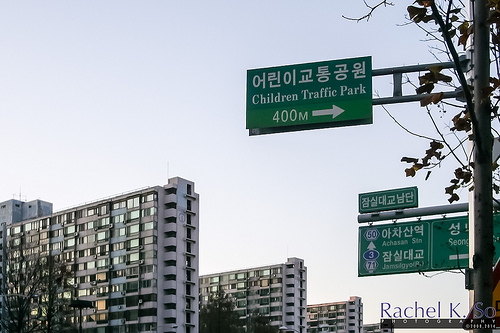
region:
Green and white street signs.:
[240, 51, 481, 286]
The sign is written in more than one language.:
[234, 45, 381, 135]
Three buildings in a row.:
[1, 171, 368, 330]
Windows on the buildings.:
[2, 192, 355, 331]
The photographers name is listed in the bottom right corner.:
[372, 297, 498, 332]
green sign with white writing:
[245, 54, 372, 134]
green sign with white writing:
[359, 185, 419, 211]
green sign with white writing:
[360, 223, 467, 280]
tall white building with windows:
[2, 178, 195, 330]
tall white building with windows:
[200, 256, 307, 331]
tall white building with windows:
[302, 295, 364, 331]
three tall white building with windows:
[0, 177, 365, 331]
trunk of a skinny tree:
[465, 0, 492, 332]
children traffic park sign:
[219, 47, 383, 142]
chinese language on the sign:
[240, 65, 370, 81]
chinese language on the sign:
[348, 185, 434, 206]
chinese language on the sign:
[378, 223, 434, 239]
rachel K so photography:
[380, 293, 497, 331]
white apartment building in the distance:
[196, 263, 321, 331]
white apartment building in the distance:
[297, 293, 375, 331]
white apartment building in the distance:
[367, 316, 398, 331]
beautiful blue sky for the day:
[50, 9, 219, 149]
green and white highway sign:
[241, 61, 383, 132]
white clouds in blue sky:
[51, 12, 83, 43]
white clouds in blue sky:
[144, 141, 175, 156]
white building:
[201, 262, 309, 319]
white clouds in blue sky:
[138, 22, 178, 73]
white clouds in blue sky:
[221, 159, 276, 190]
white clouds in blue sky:
[251, 153, 286, 201]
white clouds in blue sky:
[117, 52, 178, 107]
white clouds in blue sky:
[60, 53, 134, 108]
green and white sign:
[247, 54, 372, 134]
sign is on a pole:
[357, 186, 415, 210]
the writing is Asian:
[382, 225, 421, 237]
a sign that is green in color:
[227, 55, 392, 159]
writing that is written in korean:
[232, 55, 374, 90]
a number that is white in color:
[254, 93, 304, 137]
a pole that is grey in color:
[362, 55, 453, 117]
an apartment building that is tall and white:
[54, 159, 225, 331]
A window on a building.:
[124, 199, 139, 209]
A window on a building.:
[141, 205, 155, 213]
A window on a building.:
[141, 221, 154, 228]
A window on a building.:
[93, 258, 107, 263]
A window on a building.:
[128, 241, 138, 246]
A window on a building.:
[113, 285, 121, 291]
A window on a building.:
[262, 268, 272, 274]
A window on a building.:
[241, 273, 250, 276]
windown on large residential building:
[127, 196, 133, 208]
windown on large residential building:
[132, 197, 140, 207]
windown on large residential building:
[125, 209, 138, 219]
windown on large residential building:
[128, 223, 140, 233]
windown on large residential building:
[128, 238, 138, 248]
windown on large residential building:
[128, 251, 139, 261]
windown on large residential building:
[95, 230, 105, 239]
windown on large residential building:
[236, 272, 244, 279]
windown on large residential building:
[211, 276, 220, 284]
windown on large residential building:
[262, 269, 270, 275]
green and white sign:
[224, 40, 414, 144]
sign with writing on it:
[311, 170, 466, 300]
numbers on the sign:
[348, 228, 390, 279]